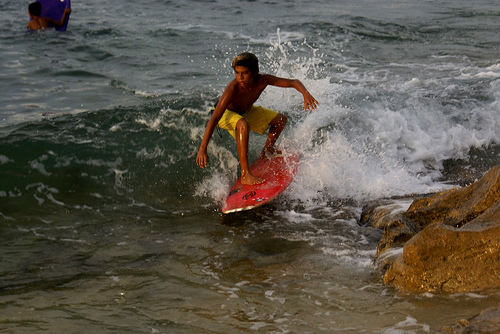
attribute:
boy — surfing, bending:
[192, 51, 325, 188]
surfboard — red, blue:
[219, 148, 297, 220]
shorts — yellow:
[208, 103, 288, 136]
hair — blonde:
[229, 51, 263, 74]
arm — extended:
[195, 79, 236, 150]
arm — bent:
[269, 69, 315, 91]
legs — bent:
[222, 108, 290, 169]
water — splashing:
[260, 48, 351, 200]